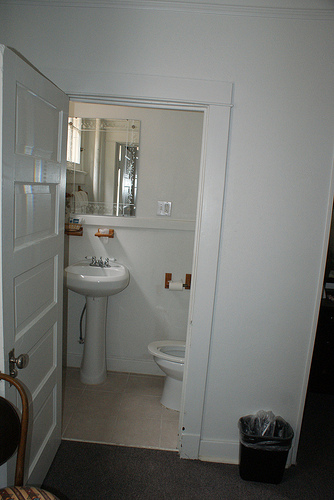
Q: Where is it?
A: This is at the bathroom.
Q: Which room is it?
A: It is a bathroom.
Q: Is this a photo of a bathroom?
A: Yes, it is showing a bathroom.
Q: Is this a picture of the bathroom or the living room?
A: It is showing the bathroom.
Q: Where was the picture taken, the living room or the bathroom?
A: It was taken at the bathroom.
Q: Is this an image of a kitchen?
A: No, the picture is showing a bathroom.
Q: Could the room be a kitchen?
A: No, it is a bathroom.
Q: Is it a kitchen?
A: No, it is a bathroom.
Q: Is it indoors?
A: Yes, it is indoors.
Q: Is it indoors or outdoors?
A: It is indoors.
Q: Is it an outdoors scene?
A: No, it is indoors.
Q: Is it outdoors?
A: No, it is indoors.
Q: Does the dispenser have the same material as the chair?
A: Yes, both the dispenser and the chair are made of wood.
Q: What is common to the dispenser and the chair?
A: The material, both the dispenser and the chair are wooden.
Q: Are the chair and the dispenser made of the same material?
A: Yes, both the chair and the dispenser are made of wood.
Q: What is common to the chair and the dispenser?
A: The material, both the chair and the dispenser are wooden.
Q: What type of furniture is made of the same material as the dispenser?
A: The chair is made of the same material as the dispenser.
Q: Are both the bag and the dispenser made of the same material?
A: No, the bag is made of plastic and the dispenser is made of wood.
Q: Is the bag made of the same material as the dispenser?
A: No, the bag is made of plastic and the dispenser is made of wood.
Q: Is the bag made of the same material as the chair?
A: No, the bag is made of plastic and the chair is made of wood.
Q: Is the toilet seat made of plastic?
A: Yes, the toilet seat is made of plastic.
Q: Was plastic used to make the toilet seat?
A: Yes, the toilet seat is made of plastic.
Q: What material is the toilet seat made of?
A: The toilet seat is made of plastic.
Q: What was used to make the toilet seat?
A: The toilet seat is made of plastic.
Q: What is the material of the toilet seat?
A: The toilet seat is made of plastic.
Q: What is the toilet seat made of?
A: The toilet seat is made of plastic.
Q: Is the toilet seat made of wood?
A: No, the toilet seat is made of plastic.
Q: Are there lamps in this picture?
A: No, there are no lamps.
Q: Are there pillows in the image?
A: No, there are no pillows.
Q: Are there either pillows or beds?
A: No, there are no pillows or beds.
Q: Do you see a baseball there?
A: No, there are no baseballs.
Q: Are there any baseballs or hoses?
A: No, there are no baseballs or hoses.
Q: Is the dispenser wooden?
A: Yes, the dispenser is wooden.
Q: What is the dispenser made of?
A: The dispenser is made of wood.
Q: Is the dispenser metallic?
A: No, the dispenser is wooden.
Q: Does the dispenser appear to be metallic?
A: No, the dispenser is wooden.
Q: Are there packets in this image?
A: No, there are no packets.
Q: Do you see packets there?
A: No, there are no packets.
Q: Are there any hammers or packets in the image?
A: No, there are no packets or hammers.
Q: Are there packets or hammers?
A: No, there are no packets or hammers.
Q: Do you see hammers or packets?
A: No, there are no packets or hammers.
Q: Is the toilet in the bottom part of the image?
A: Yes, the toilet is in the bottom of the image.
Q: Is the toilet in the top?
A: No, the toilet is in the bottom of the image.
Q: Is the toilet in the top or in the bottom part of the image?
A: The toilet is in the bottom of the image.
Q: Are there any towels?
A: Yes, there is a towel.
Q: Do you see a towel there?
A: Yes, there is a towel.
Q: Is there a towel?
A: Yes, there is a towel.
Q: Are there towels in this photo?
A: Yes, there is a towel.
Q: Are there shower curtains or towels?
A: Yes, there is a towel.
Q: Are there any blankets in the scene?
A: No, there are no blankets.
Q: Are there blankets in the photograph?
A: No, there are no blankets.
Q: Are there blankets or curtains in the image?
A: No, there are no blankets or curtains.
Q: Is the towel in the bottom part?
A: Yes, the towel is in the bottom of the image.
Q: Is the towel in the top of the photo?
A: No, the towel is in the bottom of the image.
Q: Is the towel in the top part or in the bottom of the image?
A: The towel is in the bottom of the image.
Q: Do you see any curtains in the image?
A: No, there are no curtains.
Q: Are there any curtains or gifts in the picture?
A: No, there are no curtains or gifts.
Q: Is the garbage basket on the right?
A: Yes, the garbage basket is on the right of the image.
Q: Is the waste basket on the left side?
A: No, the waste basket is on the right of the image.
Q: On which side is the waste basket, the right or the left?
A: The waste basket is on the right of the image.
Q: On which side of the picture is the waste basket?
A: The waste basket is on the right of the image.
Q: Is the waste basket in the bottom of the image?
A: Yes, the waste basket is in the bottom of the image.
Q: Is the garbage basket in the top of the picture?
A: No, the garbage basket is in the bottom of the image.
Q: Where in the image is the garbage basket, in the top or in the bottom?
A: The garbage basket is in the bottom of the image.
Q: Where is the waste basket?
A: The waste basket is on the floor.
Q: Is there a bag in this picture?
A: Yes, there is a bag.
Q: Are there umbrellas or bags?
A: Yes, there is a bag.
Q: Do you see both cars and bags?
A: No, there is a bag but no cars.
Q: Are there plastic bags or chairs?
A: Yes, there is a plastic bag.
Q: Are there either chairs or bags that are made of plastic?
A: Yes, the bag is made of plastic.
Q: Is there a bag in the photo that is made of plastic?
A: Yes, there is a bag that is made of plastic.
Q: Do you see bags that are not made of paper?
A: Yes, there is a bag that is made of plastic.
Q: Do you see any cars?
A: No, there are no cars.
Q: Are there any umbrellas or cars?
A: No, there are no cars or umbrellas.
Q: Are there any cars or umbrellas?
A: No, there are no cars or umbrellas.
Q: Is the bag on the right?
A: Yes, the bag is on the right of the image.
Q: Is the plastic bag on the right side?
A: Yes, the bag is on the right of the image.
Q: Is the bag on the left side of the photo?
A: No, the bag is on the right of the image.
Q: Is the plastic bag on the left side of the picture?
A: No, the bag is on the right of the image.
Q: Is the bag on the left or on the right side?
A: The bag is on the right of the image.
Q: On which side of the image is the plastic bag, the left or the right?
A: The bag is on the right of the image.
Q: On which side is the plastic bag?
A: The bag is on the right of the image.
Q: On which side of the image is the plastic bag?
A: The bag is on the right of the image.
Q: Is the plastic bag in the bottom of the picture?
A: Yes, the bag is in the bottom of the image.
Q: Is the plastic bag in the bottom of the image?
A: Yes, the bag is in the bottom of the image.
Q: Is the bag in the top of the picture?
A: No, the bag is in the bottom of the image.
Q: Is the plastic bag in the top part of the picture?
A: No, the bag is in the bottom of the image.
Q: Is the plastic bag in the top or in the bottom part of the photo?
A: The bag is in the bottom of the image.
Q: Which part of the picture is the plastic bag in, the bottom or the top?
A: The bag is in the bottom of the image.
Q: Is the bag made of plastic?
A: Yes, the bag is made of plastic.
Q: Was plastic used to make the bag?
A: Yes, the bag is made of plastic.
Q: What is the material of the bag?
A: The bag is made of plastic.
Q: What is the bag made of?
A: The bag is made of plastic.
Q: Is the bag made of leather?
A: No, the bag is made of plastic.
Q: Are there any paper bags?
A: No, there is a bag but it is made of plastic.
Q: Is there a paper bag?
A: No, there is a bag but it is made of plastic.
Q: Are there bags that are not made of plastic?
A: No, there is a bag but it is made of plastic.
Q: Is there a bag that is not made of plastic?
A: No, there is a bag but it is made of plastic.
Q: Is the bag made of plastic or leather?
A: The bag is made of plastic.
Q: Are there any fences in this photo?
A: No, there are no fences.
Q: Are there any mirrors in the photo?
A: Yes, there is a mirror.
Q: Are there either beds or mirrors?
A: Yes, there is a mirror.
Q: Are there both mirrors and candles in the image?
A: No, there is a mirror but no candles.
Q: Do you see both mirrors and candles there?
A: No, there is a mirror but no candles.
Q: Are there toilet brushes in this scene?
A: No, there are no toilet brushes.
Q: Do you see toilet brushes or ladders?
A: No, there are no toilet brushes or ladders.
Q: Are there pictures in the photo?
A: No, there are no pictures.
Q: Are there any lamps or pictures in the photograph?
A: No, there are no pictures or lamps.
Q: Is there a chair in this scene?
A: Yes, there is a chair.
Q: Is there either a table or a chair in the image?
A: Yes, there is a chair.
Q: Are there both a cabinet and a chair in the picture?
A: No, there is a chair but no cabinets.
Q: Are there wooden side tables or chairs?
A: Yes, there is a wood chair.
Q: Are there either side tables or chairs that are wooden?
A: Yes, the chair is wooden.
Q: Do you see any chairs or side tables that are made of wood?
A: Yes, the chair is made of wood.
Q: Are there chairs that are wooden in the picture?
A: Yes, there is a wood chair.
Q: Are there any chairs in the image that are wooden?
A: Yes, there is a chair that is wooden.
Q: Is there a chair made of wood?
A: Yes, there is a chair that is made of wood.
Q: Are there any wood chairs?
A: Yes, there is a chair that is made of wood.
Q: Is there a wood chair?
A: Yes, there is a chair that is made of wood.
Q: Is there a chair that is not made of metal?
A: Yes, there is a chair that is made of wood.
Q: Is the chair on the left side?
A: Yes, the chair is on the left of the image.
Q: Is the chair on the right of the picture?
A: No, the chair is on the left of the image.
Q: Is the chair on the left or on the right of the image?
A: The chair is on the left of the image.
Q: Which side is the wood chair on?
A: The chair is on the left of the image.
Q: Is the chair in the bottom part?
A: Yes, the chair is in the bottom of the image.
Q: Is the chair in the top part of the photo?
A: No, the chair is in the bottom of the image.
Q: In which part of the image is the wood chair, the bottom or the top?
A: The chair is in the bottom of the image.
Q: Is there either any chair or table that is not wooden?
A: No, there is a chair but it is wooden.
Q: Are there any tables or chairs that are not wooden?
A: No, there is a chair but it is wooden.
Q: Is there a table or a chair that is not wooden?
A: No, there is a chair but it is wooden.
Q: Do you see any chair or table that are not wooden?
A: No, there is a chair but it is wooden.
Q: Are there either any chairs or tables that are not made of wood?
A: No, there is a chair but it is made of wood.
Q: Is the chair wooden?
A: Yes, the chair is wooden.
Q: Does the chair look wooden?
A: Yes, the chair is wooden.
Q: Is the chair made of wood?
A: Yes, the chair is made of wood.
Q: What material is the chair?
A: The chair is made of wood.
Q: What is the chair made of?
A: The chair is made of wood.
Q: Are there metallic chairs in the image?
A: No, there is a chair but it is wooden.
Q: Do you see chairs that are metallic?
A: No, there is a chair but it is wooden.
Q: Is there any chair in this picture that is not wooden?
A: No, there is a chair but it is wooden.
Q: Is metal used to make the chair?
A: No, the chair is made of wood.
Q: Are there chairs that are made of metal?
A: No, there is a chair but it is made of wood.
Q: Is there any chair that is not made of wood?
A: No, there is a chair but it is made of wood.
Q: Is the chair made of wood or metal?
A: The chair is made of wood.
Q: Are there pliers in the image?
A: No, there are no pliers.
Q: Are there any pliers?
A: No, there are no pliers.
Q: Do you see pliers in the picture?
A: No, there are no pliers.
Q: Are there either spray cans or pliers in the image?
A: No, there are no pliers or spray cans.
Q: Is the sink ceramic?
A: Yes, the sink is ceramic.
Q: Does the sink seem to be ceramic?
A: Yes, the sink is ceramic.